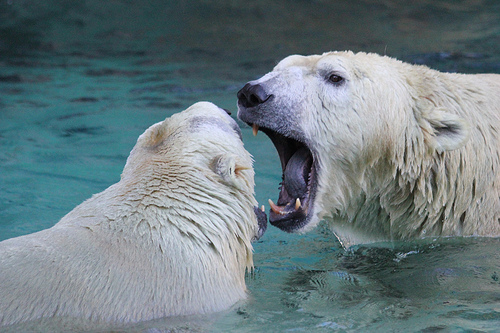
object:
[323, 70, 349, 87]
eye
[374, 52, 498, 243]
fur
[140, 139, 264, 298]
fur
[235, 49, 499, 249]
bear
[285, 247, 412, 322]
reflection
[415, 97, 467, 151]
ear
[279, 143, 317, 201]
tongue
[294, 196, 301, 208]
teeth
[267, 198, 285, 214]
teeth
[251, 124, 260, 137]
teeth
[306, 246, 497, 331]
water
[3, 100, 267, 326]
bear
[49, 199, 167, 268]
back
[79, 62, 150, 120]
water